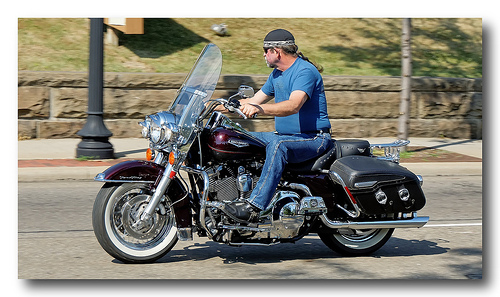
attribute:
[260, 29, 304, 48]
hat — black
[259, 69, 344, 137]
shirt — blue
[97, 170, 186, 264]
wheel — black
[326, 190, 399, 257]
wheel — black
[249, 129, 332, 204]
pants — blue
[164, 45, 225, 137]
windshield — clear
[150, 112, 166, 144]
light — silver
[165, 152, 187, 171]
turn signal — yellow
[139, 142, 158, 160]
turn signal — yellow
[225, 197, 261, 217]
boots — black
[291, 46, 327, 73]
hair — long, brown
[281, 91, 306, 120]
elbow — bent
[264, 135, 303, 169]
knee — bent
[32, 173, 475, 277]
road — black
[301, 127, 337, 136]
belt — black